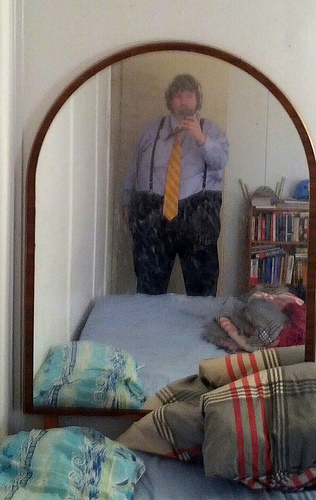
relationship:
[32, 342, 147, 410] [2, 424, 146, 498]
reflection of pillow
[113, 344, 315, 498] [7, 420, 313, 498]
blanket on bed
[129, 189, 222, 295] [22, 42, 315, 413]
black pants in mirror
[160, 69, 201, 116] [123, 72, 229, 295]
head of man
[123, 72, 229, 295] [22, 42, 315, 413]
man in mirror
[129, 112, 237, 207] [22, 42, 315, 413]
shirt in mirror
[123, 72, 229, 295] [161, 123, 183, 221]
man wearing tie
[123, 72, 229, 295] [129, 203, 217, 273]
man wearing pants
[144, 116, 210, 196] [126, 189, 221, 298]
suspenders attached to pants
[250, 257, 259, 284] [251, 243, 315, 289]
book on second shelf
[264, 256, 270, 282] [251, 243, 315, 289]
book on second shelf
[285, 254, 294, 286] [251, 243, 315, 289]
book on second shelf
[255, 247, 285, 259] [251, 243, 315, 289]
book on second shelf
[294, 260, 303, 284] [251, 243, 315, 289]
book on second shelf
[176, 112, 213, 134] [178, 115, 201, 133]
phone in man's hand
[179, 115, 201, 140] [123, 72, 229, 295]
man's hand of man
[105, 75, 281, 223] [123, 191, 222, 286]
man wearing pants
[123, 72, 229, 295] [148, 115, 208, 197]
man wearing suspenders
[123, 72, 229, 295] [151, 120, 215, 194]
man wearing black suspenders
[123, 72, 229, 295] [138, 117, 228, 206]
man wearing shirt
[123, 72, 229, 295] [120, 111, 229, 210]
man wearing shirt